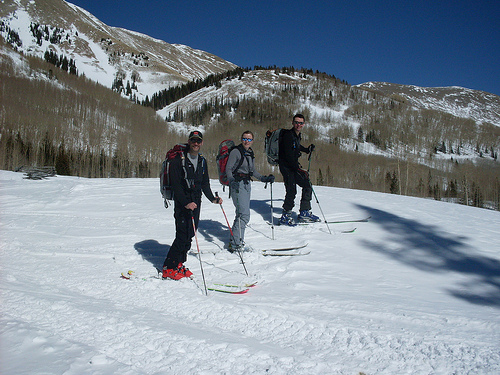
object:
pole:
[212, 190, 252, 279]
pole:
[260, 170, 278, 245]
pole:
[186, 200, 211, 299]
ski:
[119, 266, 259, 296]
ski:
[244, 240, 317, 257]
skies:
[64, 0, 498, 97]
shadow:
[347, 202, 499, 311]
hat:
[185, 129, 205, 141]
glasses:
[237, 135, 253, 143]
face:
[239, 132, 253, 149]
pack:
[263, 126, 302, 170]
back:
[274, 130, 288, 166]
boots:
[152, 262, 184, 285]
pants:
[226, 183, 251, 250]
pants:
[159, 210, 202, 269]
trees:
[355, 124, 365, 145]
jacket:
[224, 147, 269, 181]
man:
[275, 110, 321, 227]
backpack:
[214, 139, 258, 198]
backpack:
[156, 142, 206, 211]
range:
[347, 78, 499, 131]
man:
[225, 127, 274, 255]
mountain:
[154, 65, 499, 212]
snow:
[0, 169, 499, 375]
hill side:
[0, 170, 499, 374]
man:
[158, 129, 223, 281]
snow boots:
[275, 215, 300, 228]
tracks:
[0, 291, 499, 374]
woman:
[222, 129, 275, 257]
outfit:
[223, 145, 265, 245]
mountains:
[0, 0, 249, 107]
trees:
[54, 134, 72, 177]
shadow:
[193, 215, 234, 254]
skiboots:
[158, 265, 186, 282]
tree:
[386, 170, 403, 195]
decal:
[193, 130, 200, 139]